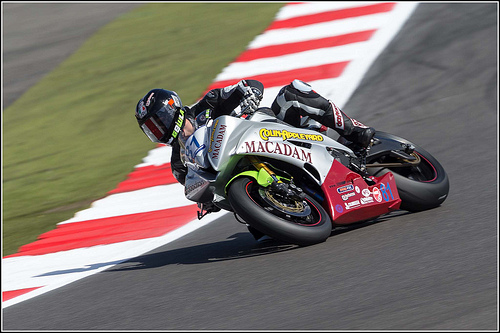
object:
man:
[135, 79, 375, 213]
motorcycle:
[184, 107, 449, 247]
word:
[259, 128, 324, 142]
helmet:
[135, 88, 186, 145]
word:
[245, 141, 312, 163]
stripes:
[0, 1, 417, 308]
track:
[1, 1, 500, 330]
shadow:
[34, 231, 298, 277]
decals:
[330, 173, 395, 213]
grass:
[2, 2, 285, 258]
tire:
[228, 174, 333, 245]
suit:
[169, 79, 376, 211]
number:
[185, 136, 205, 159]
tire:
[364, 130, 450, 210]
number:
[380, 182, 394, 201]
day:
[20, 13, 465, 295]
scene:
[0, 0, 500, 333]